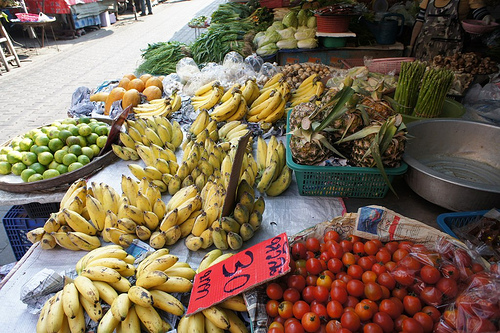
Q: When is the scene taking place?
A: Daytime.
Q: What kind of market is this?
A: Produce.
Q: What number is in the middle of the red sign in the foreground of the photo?
A: 30.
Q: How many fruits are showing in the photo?
A: Five.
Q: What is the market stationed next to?
A: Sidewalk.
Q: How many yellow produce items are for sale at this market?
A: Three.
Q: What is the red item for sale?
A: Tomatoes.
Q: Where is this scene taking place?
A: At the market.